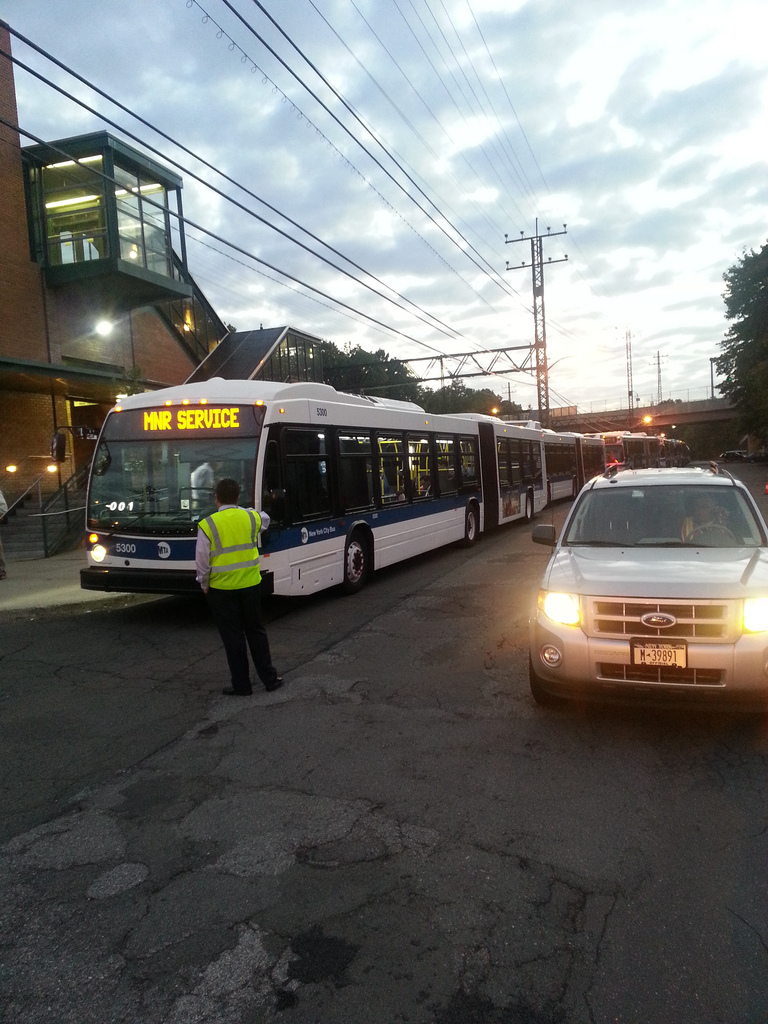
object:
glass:
[408, 433, 435, 499]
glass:
[460, 441, 479, 487]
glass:
[338, 436, 372, 453]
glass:
[436, 440, 457, 454]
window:
[113, 162, 172, 279]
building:
[0, 17, 327, 561]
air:
[0, 0, 767, 413]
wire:
[0, 16, 474, 348]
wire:
[186, 2, 569, 323]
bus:
[79, 375, 693, 596]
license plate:
[634, 643, 687, 670]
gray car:
[529, 462, 768, 716]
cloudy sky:
[206, 43, 676, 327]